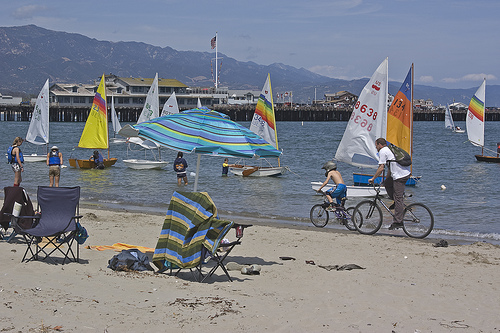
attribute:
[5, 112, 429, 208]
boats — sailing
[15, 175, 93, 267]
chair — sitting, foldable, blue, unoccupied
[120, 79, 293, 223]
umbrella — blue, purple, yellow, striped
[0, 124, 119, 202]
vest — blue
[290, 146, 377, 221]
boy — riding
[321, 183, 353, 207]
short — blue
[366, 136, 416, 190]
t-shirt — white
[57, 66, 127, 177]
boat — yellow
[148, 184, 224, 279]
towel — colorful, avacado, green, blue, gold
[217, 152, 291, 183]
person — standing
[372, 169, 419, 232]
pants — gray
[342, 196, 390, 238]
tire — black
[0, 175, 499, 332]
beach — sandy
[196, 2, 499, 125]
sky — cloudy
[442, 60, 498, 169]
rainbow — lovely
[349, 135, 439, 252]
person — riding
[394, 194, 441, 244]
wheel — rear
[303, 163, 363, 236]
person — riding